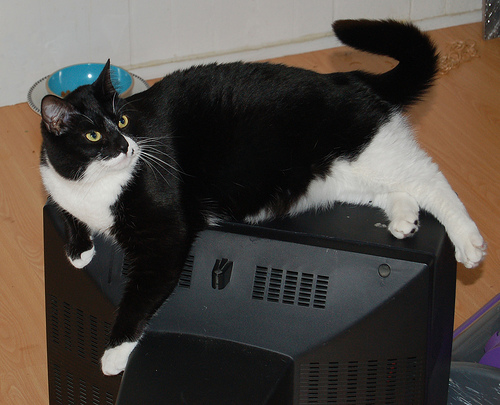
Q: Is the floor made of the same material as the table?
A: Yes, both the floor and the table are made of wood.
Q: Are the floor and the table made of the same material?
A: Yes, both the floor and the table are made of wood.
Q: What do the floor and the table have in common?
A: The material, both the floor and the table are wooden.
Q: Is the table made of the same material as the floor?
A: Yes, both the table and the floor are made of wood.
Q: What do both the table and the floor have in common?
A: The material, both the table and the floor are wooden.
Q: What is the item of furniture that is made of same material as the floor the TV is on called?
A: The piece of furniture is a table.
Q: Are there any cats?
A: Yes, there is a cat.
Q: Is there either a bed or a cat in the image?
A: Yes, there is a cat.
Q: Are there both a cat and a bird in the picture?
A: No, there is a cat but no birds.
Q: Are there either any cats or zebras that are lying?
A: Yes, the cat is lying.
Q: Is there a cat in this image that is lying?
A: Yes, there is a cat that is lying.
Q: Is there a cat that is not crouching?
A: Yes, there is a cat that is lying.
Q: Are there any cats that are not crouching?
A: Yes, there is a cat that is lying.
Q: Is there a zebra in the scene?
A: No, there are no zebras.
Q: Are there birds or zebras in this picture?
A: No, there are no zebras or birds.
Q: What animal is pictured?
A: The animal is a cat.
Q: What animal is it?
A: The animal is a cat.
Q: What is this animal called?
A: This is a cat.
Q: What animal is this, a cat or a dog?
A: This is a cat.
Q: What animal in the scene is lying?
A: The animal is a cat.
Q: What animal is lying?
A: The animal is a cat.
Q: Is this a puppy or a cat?
A: This is a cat.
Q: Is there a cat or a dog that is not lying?
A: No, there is a cat but it is lying.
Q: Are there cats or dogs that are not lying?
A: No, there is a cat but it is lying.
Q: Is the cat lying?
A: Yes, the cat is lying.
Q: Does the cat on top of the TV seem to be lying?
A: Yes, the cat is lying.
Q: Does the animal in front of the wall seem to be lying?
A: Yes, the cat is lying.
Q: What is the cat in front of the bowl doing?
A: The cat is lying.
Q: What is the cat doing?
A: The cat is lying.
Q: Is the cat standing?
A: No, the cat is lying.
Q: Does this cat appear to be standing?
A: No, the cat is lying.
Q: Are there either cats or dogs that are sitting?
A: No, there is a cat but it is lying.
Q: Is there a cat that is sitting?
A: No, there is a cat but it is lying.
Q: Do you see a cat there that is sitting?
A: No, there is a cat but it is lying.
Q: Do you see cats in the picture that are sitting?
A: No, there is a cat but it is lying.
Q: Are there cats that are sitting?
A: No, there is a cat but it is lying.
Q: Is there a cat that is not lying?
A: No, there is a cat but it is lying.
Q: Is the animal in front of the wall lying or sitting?
A: The cat is lying.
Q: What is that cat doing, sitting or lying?
A: The cat is lying.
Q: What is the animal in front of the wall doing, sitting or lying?
A: The cat is lying.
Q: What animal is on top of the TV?
A: The cat is on top of the TV.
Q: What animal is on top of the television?
A: The cat is on top of the TV.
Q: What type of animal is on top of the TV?
A: The animal is a cat.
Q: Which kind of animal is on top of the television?
A: The animal is a cat.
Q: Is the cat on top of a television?
A: Yes, the cat is on top of a television.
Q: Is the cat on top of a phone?
A: No, the cat is on top of a television.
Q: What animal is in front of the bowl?
A: The cat is in front of the bowl.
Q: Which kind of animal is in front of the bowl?
A: The animal is a cat.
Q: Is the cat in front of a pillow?
A: No, the cat is in front of a bowl.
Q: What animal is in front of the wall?
A: The animal is a cat.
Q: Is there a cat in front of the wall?
A: Yes, there is a cat in front of the wall.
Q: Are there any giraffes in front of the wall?
A: No, there is a cat in front of the wall.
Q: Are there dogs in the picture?
A: No, there are no dogs.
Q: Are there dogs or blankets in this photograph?
A: No, there are no dogs or blankets.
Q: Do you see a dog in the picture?
A: No, there are no dogs.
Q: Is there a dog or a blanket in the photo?
A: No, there are no dogs or blankets.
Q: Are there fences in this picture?
A: No, there are no fences.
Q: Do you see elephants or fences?
A: No, there are no fences or elephants.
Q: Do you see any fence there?
A: No, there are no fences.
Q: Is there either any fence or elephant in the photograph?
A: No, there are no fences or elephants.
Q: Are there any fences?
A: No, there are no fences.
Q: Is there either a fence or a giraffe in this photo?
A: No, there are no fences or giraffes.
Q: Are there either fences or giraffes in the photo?
A: No, there are no fences or giraffes.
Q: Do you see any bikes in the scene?
A: No, there are no bikes.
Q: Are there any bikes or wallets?
A: No, there are no bikes or wallets.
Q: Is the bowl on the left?
A: Yes, the bowl is on the left of the image.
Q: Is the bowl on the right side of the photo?
A: No, the bowl is on the left of the image.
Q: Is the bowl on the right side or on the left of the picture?
A: The bowl is on the left of the image.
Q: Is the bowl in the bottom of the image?
A: No, the bowl is in the top of the image.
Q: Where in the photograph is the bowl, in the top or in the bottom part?
A: The bowl is in the top of the image.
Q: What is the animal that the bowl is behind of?
A: The animal is a cat.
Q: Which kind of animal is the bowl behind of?
A: The bowl is behind the cat.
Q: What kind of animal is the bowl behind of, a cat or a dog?
A: The bowl is behind a cat.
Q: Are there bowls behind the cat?
A: Yes, there is a bowl behind the cat.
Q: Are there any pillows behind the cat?
A: No, there is a bowl behind the cat.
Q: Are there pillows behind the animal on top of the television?
A: No, there is a bowl behind the cat.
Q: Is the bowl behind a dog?
A: No, the bowl is behind a cat.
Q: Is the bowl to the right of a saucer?
A: Yes, the bowl is to the right of a saucer.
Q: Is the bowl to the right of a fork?
A: No, the bowl is to the right of a saucer.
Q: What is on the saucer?
A: The bowl is on the saucer.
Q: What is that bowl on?
A: The bowl is on the saucer.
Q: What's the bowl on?
A: The bowl is on the saucer.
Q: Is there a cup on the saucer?
A: No, there is a bowl on the saucer.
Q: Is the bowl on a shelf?
A: No, the bowl is on the saucer.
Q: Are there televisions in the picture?
A: Yes, there is a television.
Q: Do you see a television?
A: Yes, there is a television.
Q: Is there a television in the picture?
A: Yes, there is a television.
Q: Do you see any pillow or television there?
A: Yes, there is a television.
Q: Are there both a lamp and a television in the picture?
A: No, there is a television but no lamps.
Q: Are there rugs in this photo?
A: No, there are no rugs.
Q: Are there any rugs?
A: No, there are no rugs.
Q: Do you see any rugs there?
A: No, there are no rugs.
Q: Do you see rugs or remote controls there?
A: No, there are no rugs or remote controls.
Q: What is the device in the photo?
A: The device is a television.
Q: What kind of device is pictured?
A: The device is a television.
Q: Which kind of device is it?
A: The device is a television.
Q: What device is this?
A: This is a television.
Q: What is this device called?
A: This is a television.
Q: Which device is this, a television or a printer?
A: This is a television.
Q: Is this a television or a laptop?
A: This is a television.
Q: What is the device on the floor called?
A: The device is a television.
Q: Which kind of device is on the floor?
A: The device is a television.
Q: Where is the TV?
A: The TV is on the floor.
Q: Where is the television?
A: The TV is on the floor.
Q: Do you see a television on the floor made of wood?
A: Yes, there is a television on the floor.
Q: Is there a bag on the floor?
A: No, there is a television on the floor.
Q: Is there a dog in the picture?
A: No, there are no dogs.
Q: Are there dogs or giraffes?
A: No, there are no dogs or giraffes.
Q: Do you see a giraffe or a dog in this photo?
A: No, there are no dogs or giraffes.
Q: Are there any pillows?
A: No, there are no pillows.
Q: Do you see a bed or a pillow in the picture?
A: No, there are no pillows or beds.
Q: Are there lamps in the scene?
A: No, there are no lamps.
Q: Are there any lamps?
A: No, there are no lamps.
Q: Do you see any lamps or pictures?
A: No, there are no lamps or pictures.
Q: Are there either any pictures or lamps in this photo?
A: No, there are no lamps or pictures.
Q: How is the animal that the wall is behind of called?
A: The animal is a cat.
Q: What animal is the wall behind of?
A: The wall is behind the cat.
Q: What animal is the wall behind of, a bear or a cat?
A: The wall is behind a cat.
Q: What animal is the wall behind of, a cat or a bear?
A: The wall is behind a cat.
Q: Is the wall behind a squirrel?
A: No, the wall is behind the cat.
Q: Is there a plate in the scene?
A: Yes, there is a plate.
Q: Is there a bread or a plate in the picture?
A: Yes, there is a plate.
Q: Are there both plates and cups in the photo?
A: No, there is a plate but no cups.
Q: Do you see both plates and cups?
A: No, there is a plate but no cups.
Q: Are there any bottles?
A: No, there are no bottles.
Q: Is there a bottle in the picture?
A: No, there are no bottles.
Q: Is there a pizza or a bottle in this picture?
A: No, there are no bottles or pizzas.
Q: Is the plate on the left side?
A: Yes, the plate is on the left of the image.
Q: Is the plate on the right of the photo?
A: No, the plate is on the left of the image.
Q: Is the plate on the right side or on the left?
A: The plate is on the left of the image.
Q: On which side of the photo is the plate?
A: The plate is on the left of the image.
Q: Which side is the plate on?
A: The plate is on the left of the image.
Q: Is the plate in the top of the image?
A: Yes, the plate is in the top of the image.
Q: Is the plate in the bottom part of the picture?
A: No, the plate is in the top of the image.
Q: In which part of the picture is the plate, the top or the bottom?
A: The plate is in the top of the image.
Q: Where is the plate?
A: The plate is on the floor.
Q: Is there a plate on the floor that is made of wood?
A: Yes, there is a plate on the floor.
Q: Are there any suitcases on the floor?
A: No, there is a plate on the floor.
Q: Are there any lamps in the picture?
A: No, there are no lamps.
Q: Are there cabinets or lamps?
A: No, there are no lamps or cabinets.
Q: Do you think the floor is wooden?
A: Yes, the floor is wooden.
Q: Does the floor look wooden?
A: Yes, the floor is wooden.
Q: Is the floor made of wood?
A: Yes, the floor is made of wood.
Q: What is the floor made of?
A: The floor is made of wood.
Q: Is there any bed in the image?
A: No, there are no beds.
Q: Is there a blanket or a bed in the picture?
A: No, there are no beds or blankets.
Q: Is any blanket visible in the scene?
A: No, there are no blankets.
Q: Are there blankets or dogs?
A: No, there are no blankets or dogs.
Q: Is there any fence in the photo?
A: No, there are no fences.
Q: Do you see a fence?
A: No, there are no fences.